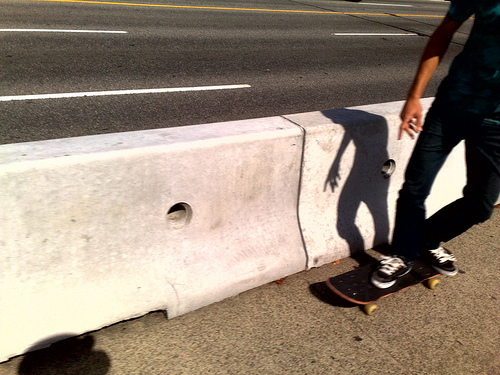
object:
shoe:
[366, 253, 415, 289]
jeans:
[389, 91, 499, 258]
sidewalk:
[180, 314, 500, 375]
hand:
[395, 99, 425, 141]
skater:
[367, 1, 497, 290]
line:
[332, 27, 419, 42]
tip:
[322, 277, 375, 306]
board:
[321, 251, 460, 316]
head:
[314, 98, 369, 124]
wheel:
[363, 300, 381, 316]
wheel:
[427, 276, 442, 290]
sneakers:
[423, 241, 461, 279]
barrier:
[0, 76, 491, 365]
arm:
[398, 0, 475, 104]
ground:
[9, 7, 397, 99]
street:
[0, 0, 474, 146]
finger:
[397, 124, 405, 141]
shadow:
[322, 106, 394, 254]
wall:
[202, 150, 283, 268]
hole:
[165, 200, 195, 232]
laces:
[378, 254, 407, 275]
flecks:
[325, 333, 391, 362]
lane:
[14, 34, 332, 83]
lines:
[3, 15, 135, 44]